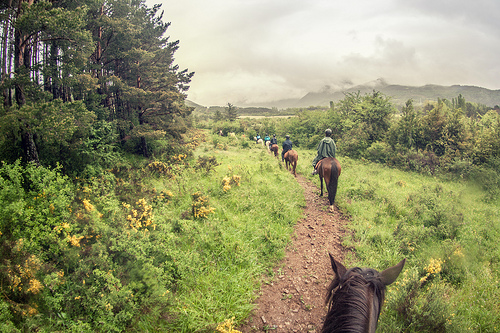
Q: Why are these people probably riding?
A: Recreation.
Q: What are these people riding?
A: Horses.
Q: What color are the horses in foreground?
A: Brown.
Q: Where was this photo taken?
A: Rural horseback trail.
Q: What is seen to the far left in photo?
A: Trees.